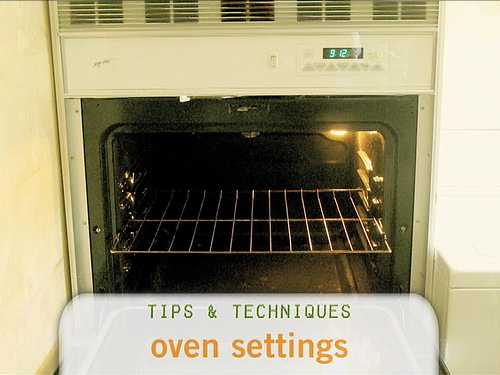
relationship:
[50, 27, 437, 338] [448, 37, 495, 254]
oven built into wall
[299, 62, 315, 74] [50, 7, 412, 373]
button on oven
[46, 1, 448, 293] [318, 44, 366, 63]
oven has display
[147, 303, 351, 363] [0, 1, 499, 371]
text on picture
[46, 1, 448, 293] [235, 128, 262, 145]
oven has light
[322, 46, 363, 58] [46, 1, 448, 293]
clock on oven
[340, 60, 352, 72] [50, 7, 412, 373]
button on oven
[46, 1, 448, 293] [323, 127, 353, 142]
oven with a light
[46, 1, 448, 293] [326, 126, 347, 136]
oven with a light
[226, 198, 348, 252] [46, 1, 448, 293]
rack in oven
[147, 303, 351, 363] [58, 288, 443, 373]
text on background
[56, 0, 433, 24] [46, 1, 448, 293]
vent above oven